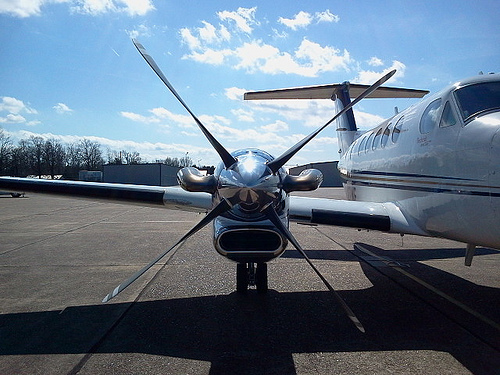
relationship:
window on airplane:
[392, 116, 403, 143] [6, 36, 498, 297]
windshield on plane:
[441, 78, 499, 130] [133, 49, 499, 279]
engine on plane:
[212, 220, 295, 268] [91, 30, 411, 348]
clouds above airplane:
[216, 11, 323, 60] [6, 36, 498, 297]